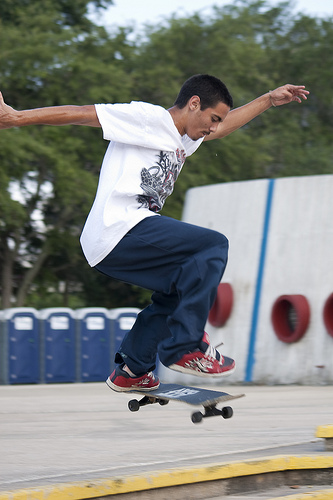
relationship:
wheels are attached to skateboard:
[125, 395, 240, 424] [116, 370, 245, 420]